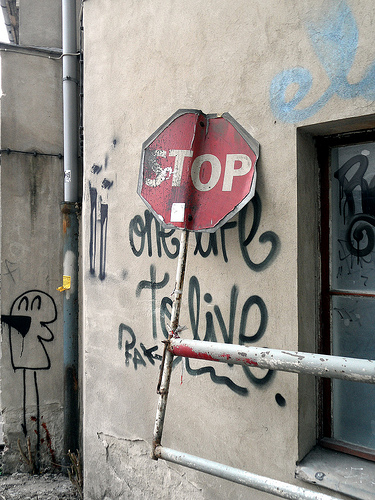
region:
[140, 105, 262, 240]
a warped stop sign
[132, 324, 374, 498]
a gray and red gate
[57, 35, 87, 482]
a gray drain pipe on the wall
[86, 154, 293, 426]
graffiti on a cement wall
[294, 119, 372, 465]
a dusty window on a wall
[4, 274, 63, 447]
black paint on a wall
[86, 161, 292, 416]
black plaint in a wall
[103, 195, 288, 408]
painted words on a wall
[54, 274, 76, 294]
a yellow tag on drain pipe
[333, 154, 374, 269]
Letters written in dusty window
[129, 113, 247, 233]
red stop sign on wall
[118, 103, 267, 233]
broken stop sign on wall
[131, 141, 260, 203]
white lettering on sign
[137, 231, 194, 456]
white post on stop sign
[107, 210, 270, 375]
black writing on a wall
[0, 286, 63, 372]
black picture on a wall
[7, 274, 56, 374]
black graffiti on a wall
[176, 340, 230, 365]
red paint on side of pole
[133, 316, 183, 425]
broken end of pole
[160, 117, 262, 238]
beat up red and white sign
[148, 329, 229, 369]
stop sign on metal gate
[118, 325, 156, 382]
black graffiti on wall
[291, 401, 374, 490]
part of frosted window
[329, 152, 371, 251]
black graffiti on window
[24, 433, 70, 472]
red stains on wall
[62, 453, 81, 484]
dry weeds by wall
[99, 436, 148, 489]
scarred and damaged wall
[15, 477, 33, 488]
gray concrete on ground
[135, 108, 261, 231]
a stop sign sitting on the wall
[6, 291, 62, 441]
some graffiti on the wall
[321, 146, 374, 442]
the window in the building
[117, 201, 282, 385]
some writing on the wall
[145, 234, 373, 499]
the poles attached to the sign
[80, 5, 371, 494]
the building with graffiti on it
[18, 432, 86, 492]
the dried out weeds on the ground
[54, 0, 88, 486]
the pole next to the building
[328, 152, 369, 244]
graffiti on the window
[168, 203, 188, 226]
a sticker on the stop sign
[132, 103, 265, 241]
an old sign STOP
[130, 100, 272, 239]
sign STOP is damaged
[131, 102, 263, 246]
the STOP is dirty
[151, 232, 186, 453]
pole of sign is rusty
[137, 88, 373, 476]
a window near a STOP sign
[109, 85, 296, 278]
the STOP sign leans on a wall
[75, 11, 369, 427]
wall is painted with black and blue letters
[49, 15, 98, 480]
a tube on the corner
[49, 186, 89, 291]
part of the tube is rusted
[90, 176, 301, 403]
black letters on a wall